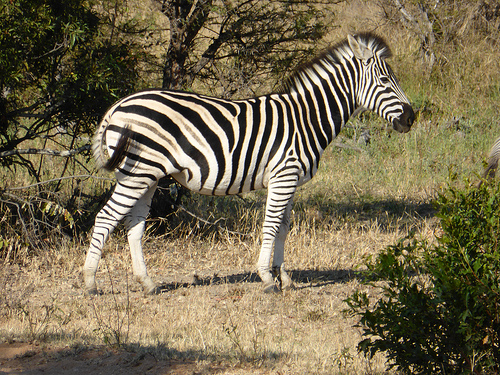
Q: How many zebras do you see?
A: 1.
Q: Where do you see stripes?
A: The zebra.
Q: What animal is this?
A: Zebra.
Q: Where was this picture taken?
A: In the wild.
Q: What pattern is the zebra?
A: Black and white stripes.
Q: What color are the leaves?
A: Green.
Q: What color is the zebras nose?
A: Black.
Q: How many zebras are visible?
A: 1.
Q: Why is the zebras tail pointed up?
A: It is in motion.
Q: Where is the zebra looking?
A: To right.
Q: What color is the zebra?
A: Black and white.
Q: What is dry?
A: Field.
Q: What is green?
A: Plant.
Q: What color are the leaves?
A: Green.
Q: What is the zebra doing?
A: Looking.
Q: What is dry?
A: Grass.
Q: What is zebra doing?
A: Standing.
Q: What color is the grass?
A: Brown.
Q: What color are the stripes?
A: Black.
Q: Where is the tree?
A: Behind zebra.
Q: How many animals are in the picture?
A: One.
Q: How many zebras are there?
A: One.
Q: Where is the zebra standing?
A: On the grass.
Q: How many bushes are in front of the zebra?
A: One.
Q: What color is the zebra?
A: Black and white.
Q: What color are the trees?
A: Green.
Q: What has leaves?
A: The trees.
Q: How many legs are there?
A: Four.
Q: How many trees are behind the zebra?
A: Three.